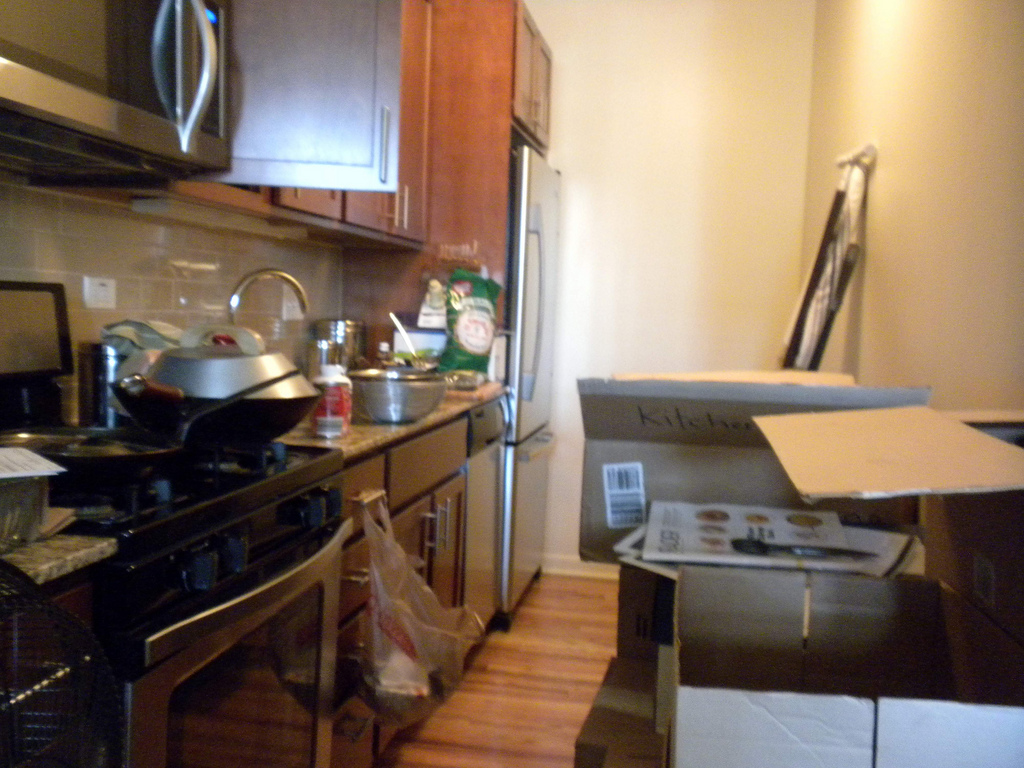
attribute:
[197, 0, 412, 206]
cabinet door — open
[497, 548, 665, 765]
floor — hardwood 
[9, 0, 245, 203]
microwave — oven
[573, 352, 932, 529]
box — cardboard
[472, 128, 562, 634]
refrigerator — stainless steel